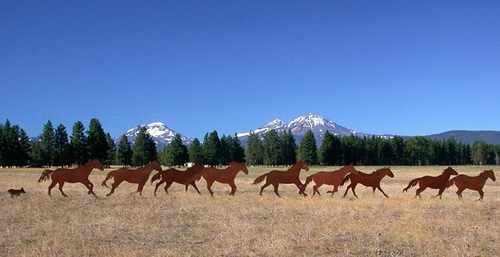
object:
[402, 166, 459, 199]
horses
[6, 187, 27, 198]
dog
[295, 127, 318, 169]
trees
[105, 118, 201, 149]
mountains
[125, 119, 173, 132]
snow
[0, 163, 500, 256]
grass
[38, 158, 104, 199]
horse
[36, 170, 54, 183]
tail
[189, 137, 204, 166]
tree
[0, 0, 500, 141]
sky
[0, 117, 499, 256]
field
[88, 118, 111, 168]
tree